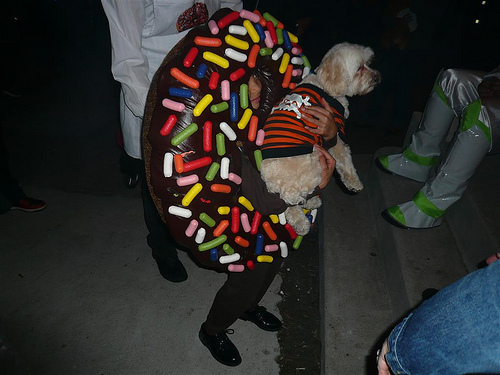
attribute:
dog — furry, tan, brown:
[257, 37, 383, 244]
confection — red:
[182, 44, 195, 67]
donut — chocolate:
[134, 10, 323, 274]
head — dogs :
[314, 35, 386, 100]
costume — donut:
[135, 7, 323, 275]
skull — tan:
[271, 90, 312, 120]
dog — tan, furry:
[257, 43, 385, 208]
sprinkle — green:
[166, 115, 213, 148]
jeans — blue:
[384, 259, 499, 374]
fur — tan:
[261, 46, 370, 196]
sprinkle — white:
[160, 152, 177, 182]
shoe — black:
[198, 325, 240, 365]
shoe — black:
[240, 308, 284, 331]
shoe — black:
[148, 243, 188, 281]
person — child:
[169, 51, 362, 369]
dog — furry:
[261, 35, 377, 198]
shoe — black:
[176, 317, 254, 374]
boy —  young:
[117, 33, 355, 302]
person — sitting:
[376, 66, 498, 230]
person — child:
[139, 6, 345, 367]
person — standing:
[99, 1, 247, 192]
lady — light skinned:
[198, 66, 338, 367]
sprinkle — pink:
[214, 75, 236, 105]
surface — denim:
[365, 252, 494, 373]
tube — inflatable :
[152, 12, 323, 289]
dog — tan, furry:
[258, 44, 377, 231]